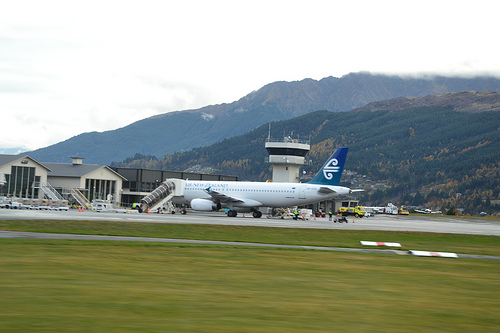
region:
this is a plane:
[113, 115, 373, 252]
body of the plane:
[152, 142, 370, 231]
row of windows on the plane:
[176, 176, 306, 208]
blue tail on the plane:
[300, 137, 354, 188]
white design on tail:
[303, 142, 355, 192]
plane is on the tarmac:
[45, 154, 498, 245]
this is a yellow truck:
[328, 190, 370, 216]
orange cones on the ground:
[63, 194, 163, 216]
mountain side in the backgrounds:
[50, 65, 495, 212]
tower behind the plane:
[252, 130, 317, 195]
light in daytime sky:
[4, 3, 496, 156]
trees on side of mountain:
[144, 94, 496, 211]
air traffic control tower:
[266, 136, 312, 180]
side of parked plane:
[142, 144, 354, 217]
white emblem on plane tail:
[314, 146, 346, 183]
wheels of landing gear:
[226, 208, 263, 218]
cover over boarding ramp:
[142, 181, 176, 210]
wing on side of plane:
[202, 186, 244, 204]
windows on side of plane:
[185, 187, 297, 194]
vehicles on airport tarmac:
[2, 196, 69, 211]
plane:
[131, 132, 368, 212]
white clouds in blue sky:
[25, 68, 83, 112]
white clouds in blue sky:
[17, 73, 35, 95]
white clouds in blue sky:
[165, 56, 220, 91]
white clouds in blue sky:
[95, 65, 135, 96]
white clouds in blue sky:
[401, 43, 438, 60]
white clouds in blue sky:
[301, 38, 361, 59]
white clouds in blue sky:
[114, 28, 222, 80]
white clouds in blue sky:
[200, 42, 241, 76]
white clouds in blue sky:
[70, 42, 141, 87]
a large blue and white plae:
[147, 157, 407, 235]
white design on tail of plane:
[313, 150, 348, 185]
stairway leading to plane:
[133, 169, 219, 244]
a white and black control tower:
[241, 122, 318, 244]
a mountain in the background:
[77, 57, 498, 239]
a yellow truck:
[335, 197, 376, 227]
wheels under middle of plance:
[223, 200, 281, 223]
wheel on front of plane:
[176, 203, 186, 222]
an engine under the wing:
[183, 189, 235, 218]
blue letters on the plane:
[184, 175, 239, 192]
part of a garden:
[446, 270, 460, 285]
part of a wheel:
[274, 215, 284, 227]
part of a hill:
[393, 149, 405, 169]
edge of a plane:
[262, 188, 268, 190]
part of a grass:
[183, 183, 188, 188]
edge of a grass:
[224, 299, 234, 314]